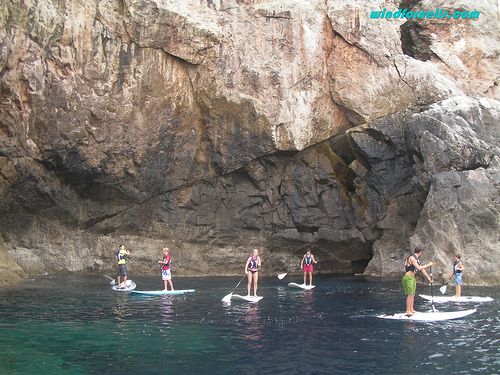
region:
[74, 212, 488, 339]
Six people have stand up paddle boards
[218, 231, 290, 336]
A woman in purple and black swimsuit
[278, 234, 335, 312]
A person with red shorts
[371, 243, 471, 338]
A person with green shorts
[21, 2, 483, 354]
A cliff juts upward out of the water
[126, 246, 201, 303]
The paddle board is blue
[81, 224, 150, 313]
The man wears a yellow shirt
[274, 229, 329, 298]
The person holds their white and black paddle out of the water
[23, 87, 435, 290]
The rock is stained black near the water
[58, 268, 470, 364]
The water is deep blue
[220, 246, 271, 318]
a girl on a paddle board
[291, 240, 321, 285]
a boy with red shorts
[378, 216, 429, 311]
a boy with green shorts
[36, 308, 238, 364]
green area in the water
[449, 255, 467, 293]
a boy with blue shorts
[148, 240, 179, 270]
a boy with a red shirt on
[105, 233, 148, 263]
a boy with a yellow shirt on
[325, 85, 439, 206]
a black are on the rock wall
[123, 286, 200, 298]
a paddle board with blue trim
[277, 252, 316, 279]
a paddle with a black shaft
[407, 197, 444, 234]
The color of this rock is a very light brown color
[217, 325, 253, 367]
The color of this water is a distinct blue-green color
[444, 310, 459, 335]
The color of this paddleboard is a very bright white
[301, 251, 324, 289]
This man is wearing a navy blue life jacket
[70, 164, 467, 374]
This photo was taken in Wisconsin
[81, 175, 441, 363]
This photo was taken in the city of Wisconsin Dells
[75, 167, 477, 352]
This photo was taken by a professional photographer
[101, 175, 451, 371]
This photo was taken with a telephoto lens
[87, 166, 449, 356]
This photo was taken during the season of summer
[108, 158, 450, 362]
This photo was taken during the month of June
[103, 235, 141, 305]
a person in the water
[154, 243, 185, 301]
a person in the water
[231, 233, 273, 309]
a person in the water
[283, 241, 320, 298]
a person in the water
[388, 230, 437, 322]
a person in the water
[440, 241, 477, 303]
a person in the water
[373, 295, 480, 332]
a white surfboard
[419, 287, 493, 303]
a white surfboard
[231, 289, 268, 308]
a white surfboard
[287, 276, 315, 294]
a white surfboard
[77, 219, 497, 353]
paddleboarding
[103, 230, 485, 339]
a group of people on paddleboards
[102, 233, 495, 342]
people stand on boards while paddling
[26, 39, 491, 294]
a rock shelf next to the water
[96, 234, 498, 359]
a group of people in the water on paddleboards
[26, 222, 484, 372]
the water is green and blue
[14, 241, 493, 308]
the water goes right up to the rock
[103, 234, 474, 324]
the people hold white and black paddles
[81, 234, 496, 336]
people standing on boards in the water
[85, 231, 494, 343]
six people on paddleboards